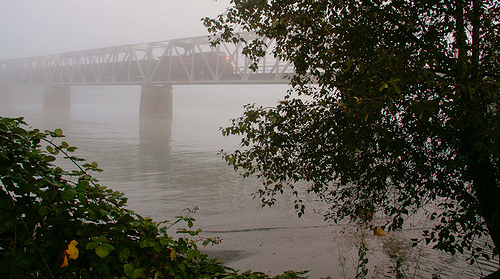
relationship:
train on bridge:
[7, 50, 237, 84] [8, 18, 345, 134]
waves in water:
[141, 143, 218, 195] [109, 116, 204, 196]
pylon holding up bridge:
[139, 83, 172, 156] [7, 35, 248, 152]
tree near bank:
[227, 12, 492, 241] [211, 219, 307, 251]